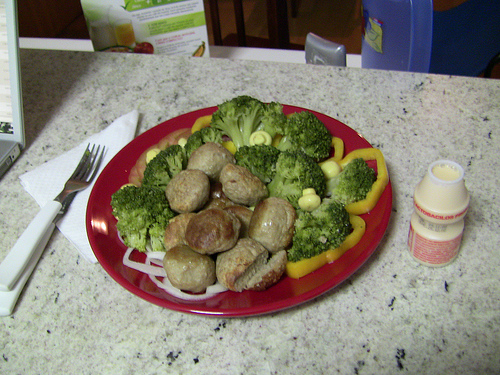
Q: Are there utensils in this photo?
A: Yes, there are utensils.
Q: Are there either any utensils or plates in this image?
A: Yes, there are utensils.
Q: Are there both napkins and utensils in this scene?
A: Yes, there are both utensils and a napkin.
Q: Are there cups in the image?
A: No, there are no cups.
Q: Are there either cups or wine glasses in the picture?
A: No, there are no cups or wine glasses.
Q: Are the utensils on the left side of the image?
A: Yes, the utensils are on the left of the image.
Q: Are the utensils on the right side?
A: No, the utensils are on the left of the image.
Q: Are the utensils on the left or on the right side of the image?
A: The utensils are on the left of the image.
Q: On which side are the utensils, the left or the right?
A: The utensils are on the left of the image.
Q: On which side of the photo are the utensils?
A: The utensils are on the left of the image.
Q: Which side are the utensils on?
A: The utensils are on the left of the image.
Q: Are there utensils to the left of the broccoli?
A: Yes, there are utensils to the left of the broccoli.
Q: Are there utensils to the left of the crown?
A: Yes, there are utensils to the left of the crown.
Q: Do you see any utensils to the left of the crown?
A: Yes, there are utensils to the left of the crown.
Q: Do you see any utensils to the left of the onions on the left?
A: Yes, there are utensils to the left of the onions.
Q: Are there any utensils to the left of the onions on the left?
A: Yes, there are utensils to the left of the onions.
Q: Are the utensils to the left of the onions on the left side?
A: Yes, the utensils are to the left of the onions.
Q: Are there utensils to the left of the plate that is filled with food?
A: Yes, there are utensils to the left of the plate.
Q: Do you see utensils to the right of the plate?
A: No, the utensils are to the left of the plate.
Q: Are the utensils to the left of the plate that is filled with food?
A: Yes, the utensils are to the left of the plate.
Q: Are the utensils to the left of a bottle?
A: No, the utensils are to the left of the plate.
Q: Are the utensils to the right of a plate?
A: No, the utensils are to the left of a plate.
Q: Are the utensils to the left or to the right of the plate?
A: The utensils are to the left of the plate.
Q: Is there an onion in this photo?
A: Yes, there are onions.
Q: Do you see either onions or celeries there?
A: Yes, there are onions.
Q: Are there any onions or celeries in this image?
A: Yes, there are onions.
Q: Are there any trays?
A: No, there are no trays.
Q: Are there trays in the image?
A: No, there are no trays.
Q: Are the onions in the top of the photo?
A: No, the onions are in the bottom of the image.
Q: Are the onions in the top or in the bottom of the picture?
A: The onions are in the bottom of the image.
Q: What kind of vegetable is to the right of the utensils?
A: The vegetables are onions.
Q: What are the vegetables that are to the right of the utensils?
A: The vegetables are onions.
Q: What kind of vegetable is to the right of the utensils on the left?
A: The vegetables are onions.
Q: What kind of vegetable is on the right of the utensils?
A: The vegetables are onions.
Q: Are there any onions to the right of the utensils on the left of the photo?
A: Yes, there are onions to the right of the utensils.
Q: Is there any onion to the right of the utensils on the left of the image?
A: Yes, there are onions to the right of the utensils.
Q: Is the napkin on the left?
A: Yes, the napkin is on the left of the image.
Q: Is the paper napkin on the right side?
A: No, the napkin is on the left of the image.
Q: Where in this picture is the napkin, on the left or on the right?
A: The napkin is on the left of the image.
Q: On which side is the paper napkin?
A: The napkin is on the left of the image.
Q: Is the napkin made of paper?
A: Yes, the napkin is made of paper.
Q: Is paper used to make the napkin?
A: Yes, the napkin is made of paper.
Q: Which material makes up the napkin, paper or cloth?
A: The napkin is made of paper.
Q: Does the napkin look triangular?
A: Yes, the napkin is triangular.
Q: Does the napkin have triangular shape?
A: Yes, the napkin is triangular.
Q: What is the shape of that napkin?
A: The napkin is triangular.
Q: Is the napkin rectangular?
A: No, the napkin is triangular.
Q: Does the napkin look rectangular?
A: No, the napkin is triangular.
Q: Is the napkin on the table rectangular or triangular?
A: The napkin is triangular.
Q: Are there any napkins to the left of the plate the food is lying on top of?
A: Yes, there is a napkin to the left of the plate.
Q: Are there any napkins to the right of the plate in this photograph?
A: No, the napkin is to the left of the plate.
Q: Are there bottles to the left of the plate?
A: No, there is a napkin to the left of the plate.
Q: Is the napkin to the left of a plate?
A: Yes, the napkin is to the left of a plate.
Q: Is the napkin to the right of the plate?
A: No, the napkin is to the left of the plate.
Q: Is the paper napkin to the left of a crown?
A: Yes, the napkin is to the left of a crown.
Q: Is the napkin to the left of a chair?
A: No, the napkin is to the left of a crown.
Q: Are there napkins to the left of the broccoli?
A: Yes, there is a napkin to the left of the broccoli.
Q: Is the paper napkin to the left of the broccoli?
A: Yes, the napkin is to the left of the broccoli.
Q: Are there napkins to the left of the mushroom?
A: Yes, there is a napkin to the left of the mushroom.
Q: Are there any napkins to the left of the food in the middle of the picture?
A: Yes, there is a napkin to the left of the mushroom.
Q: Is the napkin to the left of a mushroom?
A: Yes, the napkin is to the left of a mushroom.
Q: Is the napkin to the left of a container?
A: No, the napkin is to the left of a mushroom.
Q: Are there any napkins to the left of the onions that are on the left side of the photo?
A: Yes, there is a napkin to the left of the onions.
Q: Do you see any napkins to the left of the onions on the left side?
A: Yes, there is a napkin to the left of the onions.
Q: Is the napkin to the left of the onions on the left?
A: Yes, the napkin is to the left of the onions.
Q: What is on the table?
A: The napkin is on the table.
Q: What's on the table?
A: The napkin is on the table.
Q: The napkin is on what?
A: The napkin is on the table.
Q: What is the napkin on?
A: The napkin is on the table.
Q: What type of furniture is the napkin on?
A: The napkin is on the table.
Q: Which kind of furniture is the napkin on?
A: The napkin is on the table.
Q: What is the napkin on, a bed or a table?
A: The napkin is on a table.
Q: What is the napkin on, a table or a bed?
A: The napkin is on a table.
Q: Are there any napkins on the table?
A: Yes, there is a napkin on the table.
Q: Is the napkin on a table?
A: Yes, the napkin is on a table.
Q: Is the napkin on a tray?
A: No, the napkin is on a table.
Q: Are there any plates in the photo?
A: Yes, there is a plate.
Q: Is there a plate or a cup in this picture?
A: Yes, there is a plate.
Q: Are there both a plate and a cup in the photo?
A: No, there is a plate but no cups.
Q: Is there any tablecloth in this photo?
A: No, there are no tablecloths.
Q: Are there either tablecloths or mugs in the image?
A: No, there are no tablecloths or mugs.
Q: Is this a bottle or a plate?
A: This is a plate.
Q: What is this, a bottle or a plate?
A: This is a plate.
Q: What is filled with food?
A: The plate is filled with food.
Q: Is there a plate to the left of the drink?
A: Yes, there is a plate to the left of the drink.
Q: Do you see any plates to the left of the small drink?
A: Yes, there is a plate to the left of the drink.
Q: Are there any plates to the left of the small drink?
A: Yes, there is a plate to the left of the drink.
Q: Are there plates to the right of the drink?
A: No, the plate is to the left of the drink.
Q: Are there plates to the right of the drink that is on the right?
A: No, the plate is to the left of the drink.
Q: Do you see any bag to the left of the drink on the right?
A: No, there is a plate to the left of the drink.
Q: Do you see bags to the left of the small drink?
A: No, there is a plate to the left of the drink.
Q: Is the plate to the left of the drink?
A: Yes, the plate is to the left of the drink.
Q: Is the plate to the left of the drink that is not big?
A: Yes, the plate is to the left of the drink.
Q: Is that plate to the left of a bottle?
A: No, the plate is to the left of the drink.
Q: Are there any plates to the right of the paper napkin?
A: Yes, there is a plate to the right of the napkin.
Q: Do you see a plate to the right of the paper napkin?
A: Yes, there is a plate to the right of the napkin.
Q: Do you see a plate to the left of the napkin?
A: No, the plate is to the right of the napkin.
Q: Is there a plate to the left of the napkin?
A: No, the plate is to the right of the napkin.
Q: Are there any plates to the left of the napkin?
A: No, the plate is to the right of the napkin.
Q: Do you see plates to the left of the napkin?
A: No, the plate is to the right of the napkin.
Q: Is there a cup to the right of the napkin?
A: No, there is a plate to the right of the napkin.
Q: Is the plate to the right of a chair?
A: No, the plate is to the right of a napkin.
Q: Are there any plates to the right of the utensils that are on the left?
A: Yes, there is a plate to the right of the utensils.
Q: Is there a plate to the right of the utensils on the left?
A: Yes, there is a plate to the right of the utensils.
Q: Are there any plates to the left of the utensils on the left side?
A: No, the plate is to the right of the utensils.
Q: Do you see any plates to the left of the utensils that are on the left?
A: No, the plate is to the right of the utensils.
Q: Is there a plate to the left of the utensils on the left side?
A: No, the plate is to the right of the utensils.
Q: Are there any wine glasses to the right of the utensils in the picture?
A: No, there is a plate to the right of the utensils.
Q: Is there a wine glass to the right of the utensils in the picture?
A: No, there is a plate to the right of the utensils.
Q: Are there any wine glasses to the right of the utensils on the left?
A: No, there is a plate to the right of the utensils.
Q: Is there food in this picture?
A: Yes, there is food.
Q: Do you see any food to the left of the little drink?
A: Yes, there is food to the left of the drink.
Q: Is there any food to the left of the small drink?
A: Yes, there is food to the left of the drink.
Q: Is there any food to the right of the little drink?
A: No, the food is to the left of the drink.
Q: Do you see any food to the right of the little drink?
A: No, the food is to the left of the drink.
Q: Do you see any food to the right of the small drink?
A: No, the food is to the left of the drink.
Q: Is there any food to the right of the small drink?
A: No, the food is to the left of the drink.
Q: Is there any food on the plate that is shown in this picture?
A: Yes, there is food on the plate.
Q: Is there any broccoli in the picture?
A: Yes, there is broccoli.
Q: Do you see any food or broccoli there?
A: Yes, there is broccoli.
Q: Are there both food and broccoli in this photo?
A: Yes, there are both broccoli and food.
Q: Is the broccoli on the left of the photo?
A: Yes, the broccoli is on the left of the image.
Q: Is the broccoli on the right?
A: No, the broccoli is on the left of the image.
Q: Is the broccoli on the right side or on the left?
A: The broccoli is on the left of the image.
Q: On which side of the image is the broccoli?
A: The broccoli is on the left of the image.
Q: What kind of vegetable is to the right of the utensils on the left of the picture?
A: The vegetable is broccoli.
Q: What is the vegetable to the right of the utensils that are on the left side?
A: The vegetable is broccoli.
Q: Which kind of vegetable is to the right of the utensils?
A: The vegetable is broccoli.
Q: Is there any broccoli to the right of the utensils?
A: Yes, there is broccoli to the right of the utensils.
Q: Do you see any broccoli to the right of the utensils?
A: Yes, there is broccoli to the right of the utensils.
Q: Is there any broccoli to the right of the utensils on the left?
A: Yes, there is broccoli to the right of the utensils.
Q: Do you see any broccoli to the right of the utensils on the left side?
A: Yes, there is broccoli to the right of the utensils.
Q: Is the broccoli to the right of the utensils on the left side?
A: Yes, the broccoli is to the right of the utensils.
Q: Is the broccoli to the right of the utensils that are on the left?
A: Yes, the broccoli is to the right of the utensils.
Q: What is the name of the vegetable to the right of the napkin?
A: The vegetable is broccoli.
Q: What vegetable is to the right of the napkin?
A: The vegetable is broccoli.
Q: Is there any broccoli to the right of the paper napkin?
A: Yes, there is broccoli to the right of the napkin.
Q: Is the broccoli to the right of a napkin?
A: Yes, the broccoli is to the right of a napkin.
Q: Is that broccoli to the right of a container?
A: No, the broccoli is to the right of a napkin.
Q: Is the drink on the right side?
A: Yes, the drink is on the right of the image.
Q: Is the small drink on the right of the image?
A: Yes, the drink is on the right of the image.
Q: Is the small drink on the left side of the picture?
A: No, the drink is on the right of the image.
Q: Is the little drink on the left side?
A: No, the drink is on the right of the image.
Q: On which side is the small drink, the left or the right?
A: The drink is on the right of the image.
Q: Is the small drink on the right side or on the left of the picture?
A: The drink is on the right of the image.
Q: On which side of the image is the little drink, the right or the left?
A: The drink is on the right of the image.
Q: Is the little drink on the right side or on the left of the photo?
A: The drink is on the right of the image.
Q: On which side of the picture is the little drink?
A: The drink is on the right of the image.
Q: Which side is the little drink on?
A: The drink is on the right of the image.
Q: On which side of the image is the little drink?
A: The drink is on the right of the image.